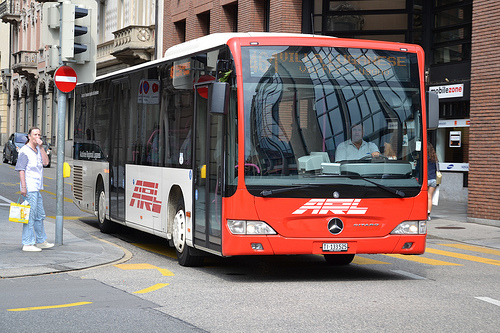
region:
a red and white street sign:
[51, 63, 81, 91]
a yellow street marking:
[411, 230, 496, 270]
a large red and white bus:
[67, 30, 435, 269]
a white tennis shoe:
[25, 242, 42, 252]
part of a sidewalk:
[0, 188, 117, 279]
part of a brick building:
[468, 0, 498, 220]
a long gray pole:
[52, 93, 68, 252]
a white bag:
[427, 187, 442, 207]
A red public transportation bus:
[58, 22, 438, 279]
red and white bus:
[55, 46, 435, 248]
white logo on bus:
[290, 181, 392, 226]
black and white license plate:
[313, 234, 354, 251]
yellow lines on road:
[353, 251, 499, 270]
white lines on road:
[480, 271, 497, 322]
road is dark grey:
[303, 288, 444, 330]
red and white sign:
[52, 69, 69, 99]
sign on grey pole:
[50, 96, 67, 269]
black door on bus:
[166, 80, 233, 226]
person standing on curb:
[19, 127, 56, 257]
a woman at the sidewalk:
[8, 110, 53, 245]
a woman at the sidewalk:
[14, 116, 74, 287]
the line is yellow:
[7, 293, 102, 323]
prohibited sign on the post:
[53, 65, 87, 98]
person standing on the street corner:
[6, 115, 72, 254]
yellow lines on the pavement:
[12, 273, 174, 318]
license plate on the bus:
[315, 238, 354, 252]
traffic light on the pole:
[50, 2, 91, 62]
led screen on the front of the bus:
[246, 47, 411, 86]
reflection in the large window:
[249, 41, 411, 152]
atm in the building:
[444, 127, 469, 154]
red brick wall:
[468, 71, 498, 208]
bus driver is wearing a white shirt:
[326, 114, 388, 177]